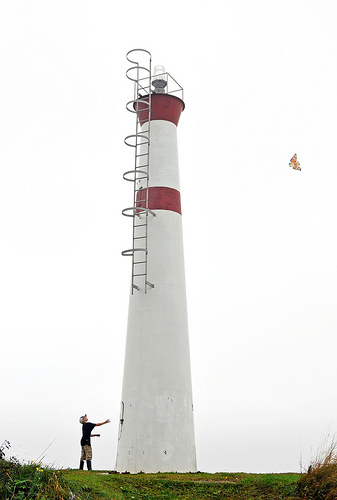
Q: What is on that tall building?
A: That is a short ladder on the lighthouse for safety.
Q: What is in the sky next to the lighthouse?
A: A kite.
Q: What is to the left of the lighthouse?
A: A person.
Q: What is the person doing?
A: Looking up.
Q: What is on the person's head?
A: A cap.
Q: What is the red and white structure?
A: A lighthouse.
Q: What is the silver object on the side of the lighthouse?
A: A ladder.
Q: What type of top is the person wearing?
A: A black shirt.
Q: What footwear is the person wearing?
A: Boots.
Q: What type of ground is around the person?
A: Grass.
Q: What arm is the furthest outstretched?
A: The person's right arm.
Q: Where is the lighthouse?
A: In a field.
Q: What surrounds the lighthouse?
A: Green grass.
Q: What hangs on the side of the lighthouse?
A: Silver railing.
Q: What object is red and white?
A: Lighthouse.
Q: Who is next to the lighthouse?
A: A man.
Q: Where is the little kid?
A: Besides a lighthouse.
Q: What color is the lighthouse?
A: White and red.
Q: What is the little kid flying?
A: A kite.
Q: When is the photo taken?
A: Daytime.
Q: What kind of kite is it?
A: Butterfly.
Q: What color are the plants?
A: Green.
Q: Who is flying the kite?
A: The kid.